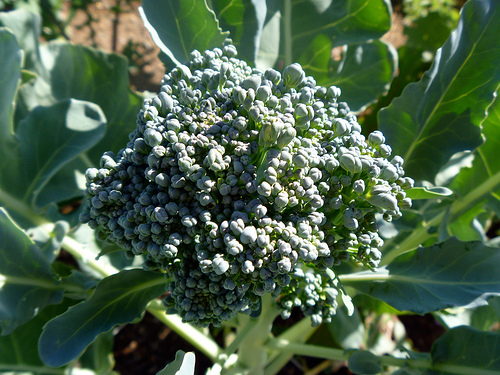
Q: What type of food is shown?
A: Broccoli.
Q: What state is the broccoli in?
A: Growing.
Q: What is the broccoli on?
A: Plant.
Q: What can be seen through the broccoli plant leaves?
A: Dirt.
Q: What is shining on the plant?
A: Sunshine.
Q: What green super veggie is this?
A: Broccoli.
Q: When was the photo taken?
A: During the daytime.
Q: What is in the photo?
A: Leaves.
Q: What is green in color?
A: The leaves.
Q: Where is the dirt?
A: Behind the leaves.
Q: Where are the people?
A: None in photo.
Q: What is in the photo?
A: Broccoli.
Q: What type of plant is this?
A: A broccoli plant.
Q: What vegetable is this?
A: Broccoli.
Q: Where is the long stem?
A: On the plant.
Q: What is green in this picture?
A: The plant.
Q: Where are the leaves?
A: On the plant.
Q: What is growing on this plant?
A: Broccoli.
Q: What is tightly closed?
A: The broccoli florets.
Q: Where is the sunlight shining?
A: On the vegetable.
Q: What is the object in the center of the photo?
A: Plant.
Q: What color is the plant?
A: Green.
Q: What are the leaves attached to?
A: Stem.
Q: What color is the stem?
A: Light green.